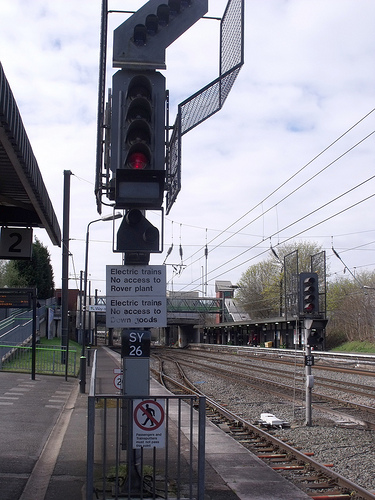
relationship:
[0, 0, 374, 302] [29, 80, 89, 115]
sky has cloud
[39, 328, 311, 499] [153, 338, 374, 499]
walkway next to train track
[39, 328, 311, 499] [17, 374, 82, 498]
walkway has gutter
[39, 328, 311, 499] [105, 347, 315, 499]
walkway has curb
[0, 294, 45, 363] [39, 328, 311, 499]
road near walkway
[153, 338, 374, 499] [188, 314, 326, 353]
train track next to platform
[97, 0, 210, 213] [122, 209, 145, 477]
traffic light on top of lightpost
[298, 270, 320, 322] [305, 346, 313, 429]
traffic light on top of lightpost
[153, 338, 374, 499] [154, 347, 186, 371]
train track has intersection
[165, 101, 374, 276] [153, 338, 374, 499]
wire above train track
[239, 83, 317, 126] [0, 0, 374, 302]
cloud in sky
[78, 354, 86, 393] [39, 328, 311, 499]
post on walkway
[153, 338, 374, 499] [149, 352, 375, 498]
train track next to train track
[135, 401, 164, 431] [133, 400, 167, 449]
no walking symbol on sign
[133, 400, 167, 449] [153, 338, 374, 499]
sign next to train track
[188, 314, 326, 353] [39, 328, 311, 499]
platform across from walkway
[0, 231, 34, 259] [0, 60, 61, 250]
sign hanging under roof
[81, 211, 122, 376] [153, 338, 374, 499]
street lamp above train track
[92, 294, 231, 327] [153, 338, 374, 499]
walking bridge over train track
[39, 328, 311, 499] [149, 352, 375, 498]
walkway next to train track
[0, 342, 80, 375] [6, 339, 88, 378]
fence in front of ground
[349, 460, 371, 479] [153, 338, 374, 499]
gravel between train track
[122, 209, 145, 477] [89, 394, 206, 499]
lightpost behind gate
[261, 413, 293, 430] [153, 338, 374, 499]
control box near train track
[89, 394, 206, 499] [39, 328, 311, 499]
gate on top of walkway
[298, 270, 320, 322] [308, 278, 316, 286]
traffic light has light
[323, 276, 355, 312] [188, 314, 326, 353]
tree behind platform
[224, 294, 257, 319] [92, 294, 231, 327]
ramp next to walking bridge